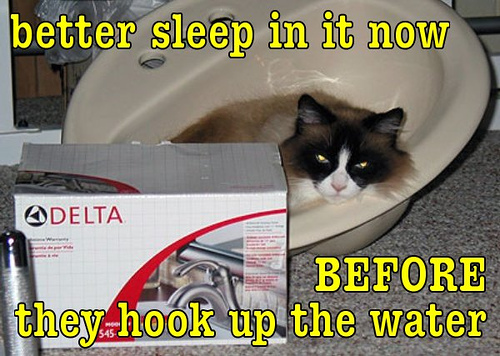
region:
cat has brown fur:
[190, 80, 410, 216]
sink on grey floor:
[75, 25, 430, 220]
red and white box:
[20, 117, 260, 352]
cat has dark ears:
[295, 75, 435, 155]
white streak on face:
[315, 165, 375, 205]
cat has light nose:
[315, 155, 360, 200]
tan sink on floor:
[85, 15, 490, 225]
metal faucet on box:
[170, 235, 276, 322]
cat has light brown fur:
[180, 105, 280, 165]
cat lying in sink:
[170, 118, 376, 224]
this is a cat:
[272, 70, 374, 187]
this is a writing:
[308, 252, 477, 303]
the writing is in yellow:
[315, 246, 473, 303]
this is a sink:
[336, 27, 481, 84]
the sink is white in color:
[418, 61, 497, 137]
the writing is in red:
[52, 202, 119, 227]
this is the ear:
[371, 100, 406, 131]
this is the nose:
[331, 174, 351, 192]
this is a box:
[46, 162, 266, 282]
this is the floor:
[426, 201, 476, 245]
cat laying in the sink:
[50, 6, 494, 263]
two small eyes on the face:
[311, 148, 376, 170]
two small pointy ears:
[289, 87, 415, 137]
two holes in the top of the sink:
[125, 6, 240, 80]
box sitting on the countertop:
[11, 138, 305, 355]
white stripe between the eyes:
[333, 143, 355, 170]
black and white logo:
[22, 203, 50, 229]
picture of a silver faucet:
[160, 253, 249, 320]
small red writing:
[244, 232, 285, 294]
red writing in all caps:
[44, 200, 126, 230]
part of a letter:
[251, 38, 261, 53]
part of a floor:
[398, 278, 417, 314]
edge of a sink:
[296, 208, 355, 305]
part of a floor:
[411, 255, 432, 287]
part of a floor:
[350, 303, 379, 344]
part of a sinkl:
[326, 230, 358, 274]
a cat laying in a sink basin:
[180, 85, 410, 202]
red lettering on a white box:
[52, 204, 127, 230]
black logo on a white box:
[23, 201, 50, 231]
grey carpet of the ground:
[408, 192, 484, 247]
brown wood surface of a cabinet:
[18, 61, 55, 93]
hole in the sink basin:
[132, 52, 175, 77]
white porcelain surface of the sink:
[382, 58, 477, 119]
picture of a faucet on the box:
[160, 245, 258, 325]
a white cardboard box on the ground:
[6, 128, 295, 343]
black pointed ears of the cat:
[288, 88, 408, 137]